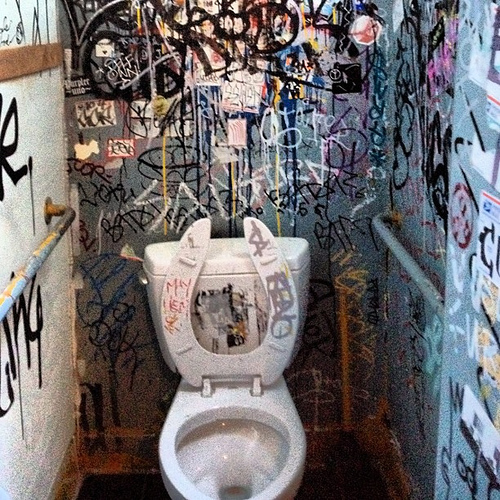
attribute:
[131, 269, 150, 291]
handle — silver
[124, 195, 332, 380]
toilet seat — underside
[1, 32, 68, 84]
board — wood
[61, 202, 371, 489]
toilet — white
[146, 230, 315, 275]
lid — ceramic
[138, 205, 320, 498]
toilet — ceramic, raised, white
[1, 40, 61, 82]
board — wooden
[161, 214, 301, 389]
seat — toilet, lifted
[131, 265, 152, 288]
handle — metal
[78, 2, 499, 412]
wall — right side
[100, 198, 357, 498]
toilet — up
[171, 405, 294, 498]
bowl area — white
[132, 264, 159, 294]
handle — steel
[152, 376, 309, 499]
bowl — toilet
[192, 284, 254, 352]
grafitti — water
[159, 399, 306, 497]
bowl — toilet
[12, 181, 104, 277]
metal rail — old, corroded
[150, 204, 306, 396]
seat — raised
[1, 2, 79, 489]
wall — side